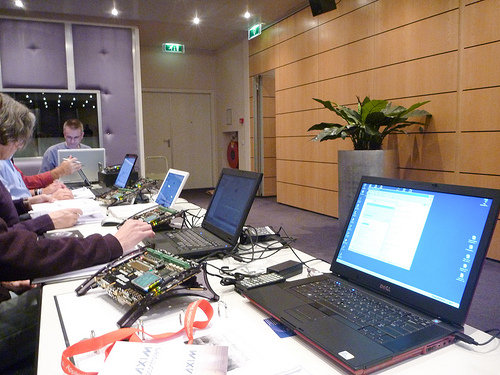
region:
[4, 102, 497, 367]
several people working with laptops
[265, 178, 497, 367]
the open screen of a laptop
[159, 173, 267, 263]
the open screen of a laptop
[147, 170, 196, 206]
the open screen of a laptop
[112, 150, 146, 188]
the open screen of a laptop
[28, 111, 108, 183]
a man working at a laptop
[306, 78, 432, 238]
a large potted plant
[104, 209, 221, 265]
the hand of a person at a laptop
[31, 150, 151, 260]
several hands on a table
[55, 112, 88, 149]
a man wearing glasses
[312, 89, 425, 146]
a plant next to the wall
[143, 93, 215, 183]
a white door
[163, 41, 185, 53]
an exit sign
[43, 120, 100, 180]
a man looking at a computer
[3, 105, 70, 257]
people sitting at the table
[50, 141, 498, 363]
laptops on a table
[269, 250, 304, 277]
a laptop charger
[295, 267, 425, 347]
the keyboard of the laptop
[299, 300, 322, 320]
the mouse pad of the laptop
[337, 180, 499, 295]
the screen of the laptop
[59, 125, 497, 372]
laptops on the table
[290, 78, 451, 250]
green plant in a tall silver planter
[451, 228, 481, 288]
icons on the desktop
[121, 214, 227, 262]
hand hovering over the keyboard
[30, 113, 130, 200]
man sitting at the end of the table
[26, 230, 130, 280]
arm resting on the table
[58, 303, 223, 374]
orange lanyard on the table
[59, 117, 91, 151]
head is tilted down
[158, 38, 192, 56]
green and white sign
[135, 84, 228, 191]
double doors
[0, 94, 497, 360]
several people working on laptop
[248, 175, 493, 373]
the open screen of a laptop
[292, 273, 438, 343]
the keyboard of a laptop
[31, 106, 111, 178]
a man working at his laptop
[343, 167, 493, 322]
the screen of a laptop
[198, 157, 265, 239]
the screen of a laptop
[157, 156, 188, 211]
the screen of a laptop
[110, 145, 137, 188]
the screen of a laptop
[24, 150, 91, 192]
the hand of someone opening a laptop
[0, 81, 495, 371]
several people working with computers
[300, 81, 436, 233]
lovely potted plant decorates the room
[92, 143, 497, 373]
all these laptop computers are turned on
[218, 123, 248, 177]
fire hose located at one end of the room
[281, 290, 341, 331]
this laptop computer has a touch pad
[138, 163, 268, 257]
this laptop computer is black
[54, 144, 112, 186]
this laptop computer is silver